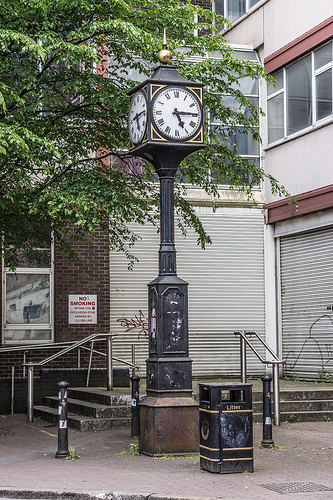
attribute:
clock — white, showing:
[155, 81, 200, 137]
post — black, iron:
[147, 148, 190, 397]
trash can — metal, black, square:
[200, 381, 254, 475]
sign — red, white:
[71, 291, 94, 324]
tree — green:
[1, 2, 299, 271]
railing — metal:
[233, 330, 287, 426]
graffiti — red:
[119, 309, 151, 334]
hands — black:
[176, 105, 199, 128]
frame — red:
[258, 20, 331, 72]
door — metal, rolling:
[272, 227, 330, 379]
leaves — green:
[21, 42, 50, 63]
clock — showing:
[125, 90, 144, 140]